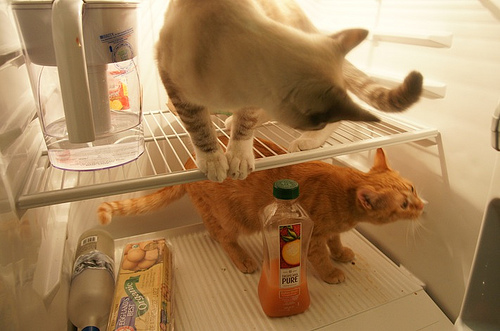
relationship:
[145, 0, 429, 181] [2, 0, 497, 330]
cat in kitchen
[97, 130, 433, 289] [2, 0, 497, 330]
cat in kitchen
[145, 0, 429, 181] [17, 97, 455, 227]
cat on wire shelf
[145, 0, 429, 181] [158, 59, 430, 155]
cat has stripes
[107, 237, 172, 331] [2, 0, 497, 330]
carton are in kitchen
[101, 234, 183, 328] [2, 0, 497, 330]
carton in kitchen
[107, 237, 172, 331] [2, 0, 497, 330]
carton in kitchen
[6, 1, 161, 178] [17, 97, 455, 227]
pitcher on wire shelf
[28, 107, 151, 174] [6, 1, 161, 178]
water in pitcher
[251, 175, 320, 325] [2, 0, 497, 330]
bottle in kitchen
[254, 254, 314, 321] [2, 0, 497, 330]
orange juice in kitchen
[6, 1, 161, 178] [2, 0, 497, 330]
pitcher in kitchen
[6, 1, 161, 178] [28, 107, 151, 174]
pitcher has water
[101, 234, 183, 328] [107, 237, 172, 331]
carton has carton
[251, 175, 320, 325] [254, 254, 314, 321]
bottle has orange juice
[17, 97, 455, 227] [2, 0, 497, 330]
wire shelf in kitchen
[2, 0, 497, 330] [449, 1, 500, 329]
kitchen has door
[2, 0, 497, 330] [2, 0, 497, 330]
kitchen in kitchen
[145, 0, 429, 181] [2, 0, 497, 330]
cat playing in kitchen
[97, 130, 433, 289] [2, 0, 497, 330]
cat playing in kitchen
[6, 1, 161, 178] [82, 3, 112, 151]
pitcher has filter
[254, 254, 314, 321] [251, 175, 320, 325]
orange juice in bottle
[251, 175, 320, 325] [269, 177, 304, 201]
bottle has lid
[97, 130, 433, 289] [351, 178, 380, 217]
cat has ear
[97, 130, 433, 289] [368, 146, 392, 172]
cat has ear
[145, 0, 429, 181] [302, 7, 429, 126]
cat has tail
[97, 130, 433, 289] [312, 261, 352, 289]
cat has paw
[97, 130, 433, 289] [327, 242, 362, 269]
cat has paw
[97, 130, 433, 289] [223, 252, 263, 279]
cat has paw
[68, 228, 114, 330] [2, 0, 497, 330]
bottle in kitchen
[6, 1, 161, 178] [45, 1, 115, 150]
pitcher has handle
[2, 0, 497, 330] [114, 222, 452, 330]
kitchen has shelf